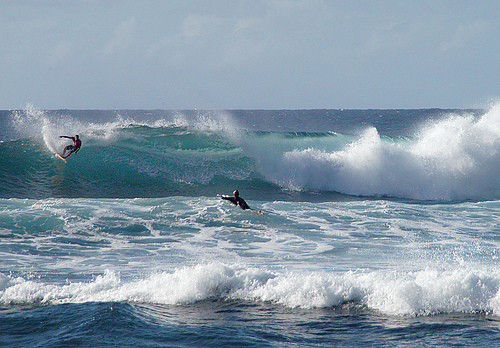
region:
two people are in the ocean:
[42, 107, 284, 218]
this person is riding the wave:
[38, 123, 96, 168]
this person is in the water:
[206, 188, 276, 224]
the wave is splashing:
[290, 112, 495, 206]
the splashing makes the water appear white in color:
[26, 268, 493, 313]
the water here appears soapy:
[46, 202, 473, 279]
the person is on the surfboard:
[50, 148, 68, 165]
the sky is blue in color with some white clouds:
[5, 5, 481, 108]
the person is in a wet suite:
[218, 192, 258, 217]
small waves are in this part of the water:
[11, 304, 489, 341]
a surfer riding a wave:
[23, 101, 204, 183]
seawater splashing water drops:
[6, 103, 63, 126]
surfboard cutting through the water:
[34, 138, 66, 164]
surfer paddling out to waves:
[209, 181, 292, 243]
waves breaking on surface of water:
[10, 245, 489, 324]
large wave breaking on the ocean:
[271, 85, 496, 235]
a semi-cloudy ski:
[9, 3, 489, 88]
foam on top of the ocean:
[34, 209, 411, 259]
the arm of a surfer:
[53, 125, 72, 142]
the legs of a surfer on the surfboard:
[51, 145, 73, 167]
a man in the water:
[218, 189, 269, 216]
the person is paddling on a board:
[215, 190, 266, 215]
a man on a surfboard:
[51, 131, 82, 161]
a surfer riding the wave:
[47, 128, 95, 165]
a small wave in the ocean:
[0, 260, 492, 312]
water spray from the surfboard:
[27, 108, 61, 149]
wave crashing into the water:
[248, 122, 456, 202]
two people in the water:
[56, 130, 261, 215]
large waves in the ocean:
[8, 108, 488, 314]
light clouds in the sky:
[91, 17, 283, 85]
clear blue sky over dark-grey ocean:
[2, 5, 492, 122]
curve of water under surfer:
[31, 110, 81, 165]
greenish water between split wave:
[90, 110, 240, 165]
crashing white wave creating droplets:
[265, 110, 495, 200]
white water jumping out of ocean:
[5, 100, 235, 130]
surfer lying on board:
[215, 181, 265, 216]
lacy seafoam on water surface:
[31, 205, 456, 255]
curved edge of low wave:
[106, 270, 493, 322]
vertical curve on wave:
[350, 115, 385, 192]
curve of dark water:
[247, 120, 330, 142]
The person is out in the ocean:
[26, 33, 171, 301]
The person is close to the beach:
[12, 60, 182, 325]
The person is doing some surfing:
[25, 55, 201, 315]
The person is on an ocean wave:
[22, 40, 184, 320]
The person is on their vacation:
[21, 30, 191, 335]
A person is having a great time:
[33, 43, 175, 328]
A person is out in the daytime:
[17, 67, 187, 307]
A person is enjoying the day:
[34, 70, 183, 305]